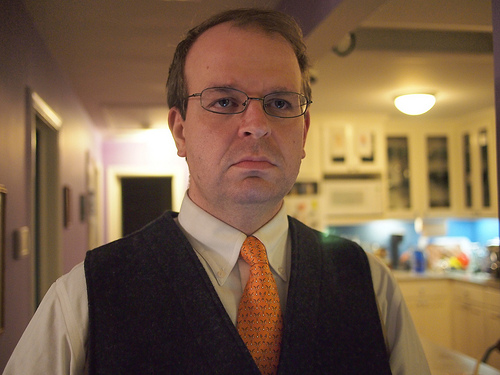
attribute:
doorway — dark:
[117, 175, 176, 237]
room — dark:
[2, 5, 497, 363]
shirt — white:
[4, 194, 455, 374]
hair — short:
[161, 2, 311, 125]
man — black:
[12, 5, 427, 373]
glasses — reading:
[183, 79, 312, 124]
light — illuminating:
[383, 87, 448, 135]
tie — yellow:
[221, 244, 318, 348]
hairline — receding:
[177, 16, 307, 79]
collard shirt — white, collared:
[177, 198, 257, 335]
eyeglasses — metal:
[188, 85, 314, 117]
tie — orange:
[217, 235, 298, 373]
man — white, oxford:
[38, 15, 495, 374]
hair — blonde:
[238, 7, 280, 34]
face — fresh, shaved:
[189, 39, 305, 206]